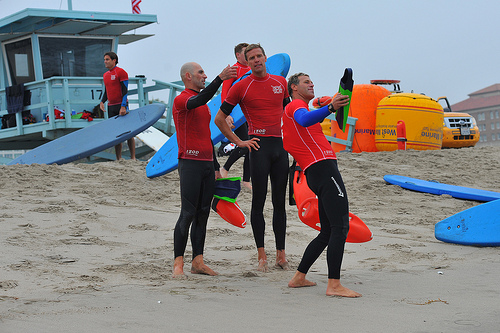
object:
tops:
[171, 88, 214, 161]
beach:
[0, 145, 499, 332]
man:
[99, 52, 136, 163]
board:
[5, 102, 167, 168]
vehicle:
[436, 97, 481, 150]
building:
[0, 7, 221, 165]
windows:
[38, 37, 113, 79]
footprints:
[62, 201, 122, 261]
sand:
[0, 243, 499, 333]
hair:
[287, 72, 310, 99]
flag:
[131, 0, 145, 13]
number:
[89, 87, 106, 100]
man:
[279, 72, 362, 299]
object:
[369, 80, 404, 94]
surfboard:
[382, 174, 500, 203]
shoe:
[213, 176, 242, 203]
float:
[298, 196, 373, 245]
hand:
[329, 92, 351, 110]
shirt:
[101, 67, 131, 106]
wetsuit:
[172, 87, 222, 258]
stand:
[1, 0, 182, 163]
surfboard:
[4, 102, 168, 168]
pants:
[173, 157, 219, 259]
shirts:
[226, 73, 292, 139]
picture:
[0, 0, 499, 333]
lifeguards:
[171, 61, 238, 279]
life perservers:
[210, 176, 247, 229]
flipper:
[331, 68, 356, 136]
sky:
[163, 0, 500, 72]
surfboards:
[432, 199, 500, 247]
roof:
[383, 93, 435, 99]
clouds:
[165, 0, 500, 78]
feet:
[171, 256, 187, 280]